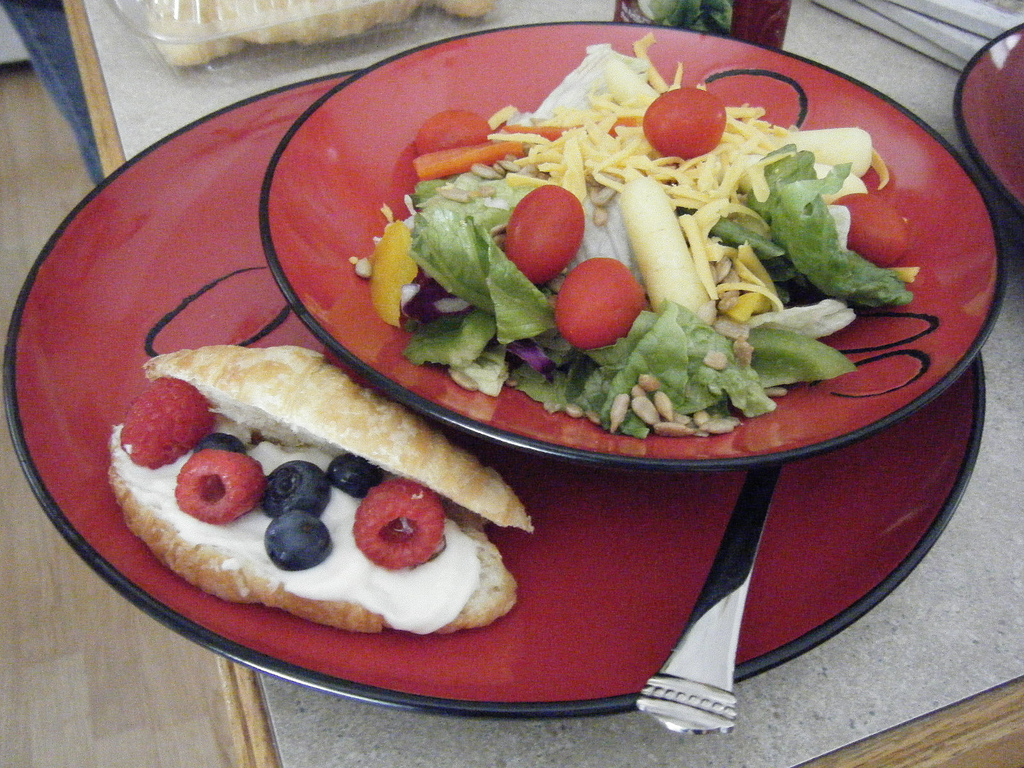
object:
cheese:
[607, 82, 782, 238]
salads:
[427, 84, 885, 394]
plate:
[2, 24, 1021, 720]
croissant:
[109, 341, 538, 629]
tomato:
[506, 184, 585, 286]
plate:
[257, 19, 1012, 468]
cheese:
[676, 208, 720, 295]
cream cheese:
[109, 402, 517, 641]